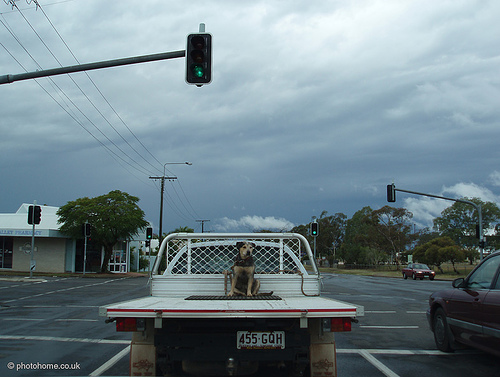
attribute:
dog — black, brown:
[224, 238, 275, 298]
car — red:
[400, 260, 437, 278]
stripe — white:
[351, 341, 436, 374]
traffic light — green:
[185, 36, 212, 86]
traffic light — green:
[385, 178, 395, 200]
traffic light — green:
[141, 222, 153, 244]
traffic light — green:
[307, 220, 319, 238]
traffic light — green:
[181, 28, 216, 89]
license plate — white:
[234, 324, 287, 354]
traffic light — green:
[185, 32, 210, 84]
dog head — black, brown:
[232, 236, 256, 261]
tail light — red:
[327, 319, 354, 333]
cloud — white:
[207, 215, 292, 235]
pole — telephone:
[140, 142, 177, 245]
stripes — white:
[338, 320, 443, 371]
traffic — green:
[180, 20, 216, 91]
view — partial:
[6, 217, 484, 297]